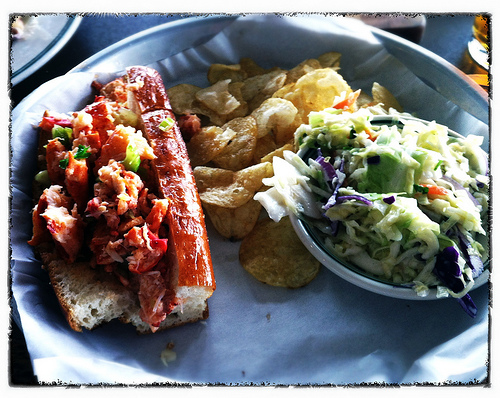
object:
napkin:
[15, 314, 498, 377]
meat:
[113, 230, 161, 270]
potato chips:
[191, 161, 260, 211]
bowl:
[287, 122, 492, 301]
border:
[16, 17, 79, 78]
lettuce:
[334, 118, 352, 133]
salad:
[325, 149, 336, 156]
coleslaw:
[411, 218, 433, 239]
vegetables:
[124, 131, 149, 173]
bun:
[31, 78, 212, 337]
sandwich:
[37, 63, 217, 332]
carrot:
[419, 183, 450, 199]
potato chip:
[233, 227, 320, 289]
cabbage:
[372, 147, 407, 180]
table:
[26, 17, 498, 285]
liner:
[149, 31, 410, 78]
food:
[37, 52, 499, 331]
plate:
[21, 16, 484, 381]